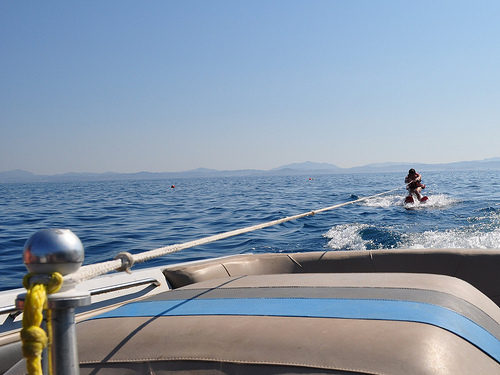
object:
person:
[400, 167, 430, 208]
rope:
[23, 182, 436, 277]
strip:
[83, 297, 499, 362]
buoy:
[170, 184, 178, 191]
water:
[0, 176, 500, 265]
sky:
[3, 2, 500, 161]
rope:
[19, 272, 61, 374]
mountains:
[0, 155, 500, 181]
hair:
[407, 168, 415, 174]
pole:
[19, 228, 95, 374]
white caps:
[325, 221, 492, 250]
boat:
[0, 250, 500, 374]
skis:
[405, 193, 429, 204]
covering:
[68, 272, 497, 374]